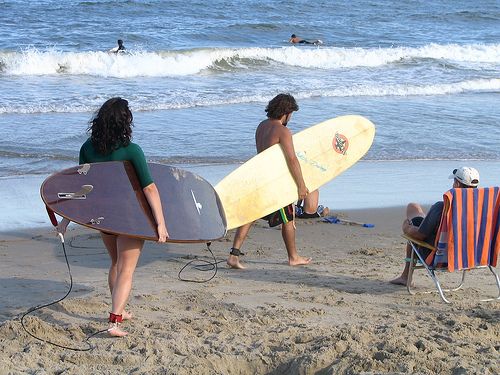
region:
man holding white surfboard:
[218, 88, 380, 275]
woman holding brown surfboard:
[26, 83, 232, 347]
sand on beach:
[0, 201, 495, 373]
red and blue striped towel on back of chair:
[421, 181, 499, 279]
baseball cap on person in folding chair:
[446, 162, 483, 189]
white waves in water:
[2, 40, 499, 97]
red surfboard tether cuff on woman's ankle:
[102, 309, 127, 328]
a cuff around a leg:
[99, 296, 135, 342]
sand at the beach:
[233, 310, 308, 345]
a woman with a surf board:
[81, 112, 183, 247]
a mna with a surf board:
[250, 93, 326, 203]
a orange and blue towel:
[435, 203, 491, 274]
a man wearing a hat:
[433, 164, 498, 200]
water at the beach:
[387, 122, 456, 164]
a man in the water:
[104, 33, 156, 70]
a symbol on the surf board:
[323, 127, 368, 163]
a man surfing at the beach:
[272, 16, 341, 62]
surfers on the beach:
[11, 15, 348, 358]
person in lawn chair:
[378, 138, 495, 340]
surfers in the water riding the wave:
[10, 65, 418, 371]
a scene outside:
[10, 5, 495, 373]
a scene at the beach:
[4, 3, 484, 374]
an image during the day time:
[4, 6, 483, 373]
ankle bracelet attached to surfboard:
[22, 210, 145, 357]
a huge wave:
[7, 41, 497, 89]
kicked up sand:
[21, 294, 498, 373]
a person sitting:
[290, 173, 345, 227]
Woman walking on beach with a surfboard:
[41, 95, 227, 338]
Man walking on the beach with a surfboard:
[213, 89, 378, 268]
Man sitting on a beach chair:
[391, 165, 498, 304]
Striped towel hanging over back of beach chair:
[426, 184, 498, 276]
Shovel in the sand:
[322, 211, 380, 230]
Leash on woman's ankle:
[104, 307, 125, 328]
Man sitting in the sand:
[296, 179, 324, 221]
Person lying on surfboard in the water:
[281, 32, 325, 49]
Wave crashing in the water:
[7, 33, 498, 82]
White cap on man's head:
[448, 163, 483, 184]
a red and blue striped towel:
[451, 187, 498, 262]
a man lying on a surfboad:
[276, 12, 338, 51]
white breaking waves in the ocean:
[8, 49, 498, 73]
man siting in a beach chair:
[404, 160, 496, 307]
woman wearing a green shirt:
[41, 98, 226, 353]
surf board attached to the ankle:
[31, 157, 209, 353]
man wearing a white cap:
[443, 163, 479, 184]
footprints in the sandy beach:
[162, 286, 467, 373]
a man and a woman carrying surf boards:
[39, 84, 351, 315]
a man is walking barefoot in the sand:
[223, 230, 323, 277]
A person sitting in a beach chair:
[401, 162, 498, 302]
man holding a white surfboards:
[215, 88, 374, 273]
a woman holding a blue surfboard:
[30, 93, 226, 335]